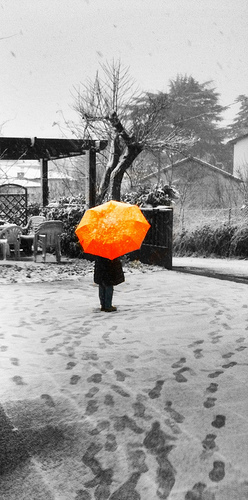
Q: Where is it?
A: This is at the pavement.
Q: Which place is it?
A: It is a pavement.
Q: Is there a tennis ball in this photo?
A: No, there are no tennis balls.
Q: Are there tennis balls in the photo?
A: No, there are no tennis balls.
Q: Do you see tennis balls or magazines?
A: No, there are no tennis balls or magazines.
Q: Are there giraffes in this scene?
A: No, there are no giraffes.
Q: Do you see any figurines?
A: No, there are no figurines.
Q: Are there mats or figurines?
A: No, there are no figurines or mats.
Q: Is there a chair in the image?
A: Yes, there is a chair.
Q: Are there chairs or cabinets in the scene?
A: Yes, there is a chair.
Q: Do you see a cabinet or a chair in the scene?
A: Yes, there is a chair.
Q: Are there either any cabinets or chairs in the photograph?
A: Yes, there is a chair.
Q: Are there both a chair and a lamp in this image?
A: No, there is a chair but no lamps.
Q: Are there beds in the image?
A: No, there are no beds.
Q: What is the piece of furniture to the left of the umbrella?
A: The piece of furniture is a chair.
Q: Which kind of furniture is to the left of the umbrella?
A: The piece of furniture is a chair.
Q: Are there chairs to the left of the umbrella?
A: Yes, there is a chair to the left of the umbrella.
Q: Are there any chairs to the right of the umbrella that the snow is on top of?
A: No, the chair is to the left of the umbrella.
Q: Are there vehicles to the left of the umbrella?
A: No, there is a chair to the left of the umbrella.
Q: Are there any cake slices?
A: No, there are no cake slices.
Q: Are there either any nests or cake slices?
A: No, there are no cake slices or nests.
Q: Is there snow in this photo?
A: Yes, there is snow.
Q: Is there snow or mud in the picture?
A: Yes, there is snow.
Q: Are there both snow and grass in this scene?
A: No, there is snow but no grass.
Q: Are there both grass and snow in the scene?
A: No, there is snow but no grass.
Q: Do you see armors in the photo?
A: No, there are no armors.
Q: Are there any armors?
A: No, there are no armors.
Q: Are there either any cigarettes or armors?
A: No, there are no armors or cigarettes.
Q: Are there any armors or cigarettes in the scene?
A: No, there are no armors or cigarettes.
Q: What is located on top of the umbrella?
A: The snow is on top of the umbrella.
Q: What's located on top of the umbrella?
A: The snow is on top of the umbrella.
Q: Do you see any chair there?
A: Yes, there is a chair.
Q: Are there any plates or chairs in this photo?
A: Yes, there is a chair.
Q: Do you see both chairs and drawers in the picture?
A: No, there is a chair but no drawers.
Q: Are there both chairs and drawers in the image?
A: No, there is a chair but no drawers.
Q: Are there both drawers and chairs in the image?
A: No, there is a chair but no drawers.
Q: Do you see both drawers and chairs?
A: No, there is a chair but no drawers.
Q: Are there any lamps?
A: No, there are no lamps.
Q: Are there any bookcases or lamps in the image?
A: No, there are no lamps or bookcases.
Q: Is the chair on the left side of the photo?
A: Yes, the chair is on the left of the image.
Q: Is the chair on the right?
A: No, the chair is on the left of the image.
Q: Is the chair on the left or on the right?
A: The chair is on the left of the image.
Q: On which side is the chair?
A: The chair is on the left of the image.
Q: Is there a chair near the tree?
A: Yes, there is a chair near the tree.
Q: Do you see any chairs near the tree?
A: Yes, there is a chair near the tree.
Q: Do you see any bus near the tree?
A: No, there is a chair near the tree.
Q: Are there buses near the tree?
A: No, there is a chair near the tree.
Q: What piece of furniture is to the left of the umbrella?
A: The piece of furniture is a chair.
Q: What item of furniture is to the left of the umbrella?
A: The piece of furniture is a chair.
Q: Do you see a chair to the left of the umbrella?
A: Yes, there is a chair to the left of the umbrella.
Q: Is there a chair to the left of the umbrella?
A: Yes, there is a chair to the left of the umbrella.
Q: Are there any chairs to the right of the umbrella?
A: No, the chair is to the left of the umbrella.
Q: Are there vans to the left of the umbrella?
A: No, there is a chair to the left of the umbrella.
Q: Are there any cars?
A: No, there are no cars.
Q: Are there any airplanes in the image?
A: No, there are no airplanes.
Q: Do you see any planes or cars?
A: No, there are no planes or cars.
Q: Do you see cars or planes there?
A: No, there are no planes or cars.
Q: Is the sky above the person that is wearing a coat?
A: Yes, the sky is above the person.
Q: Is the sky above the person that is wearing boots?
A: Yes, the sky is above the person.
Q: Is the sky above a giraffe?
A: No, the sky is above the person.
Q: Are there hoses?
A: No, there are no hoses.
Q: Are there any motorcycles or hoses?
A: No, there are no hoses or motorcycles.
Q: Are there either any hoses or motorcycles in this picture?
A: No, there are no hoses or motorcycles.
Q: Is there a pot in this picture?
A: No, there are no pots.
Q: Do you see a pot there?
A: No, there are no pots.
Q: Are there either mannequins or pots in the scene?
A: No, there are no pots or mannequins.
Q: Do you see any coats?
A: Yes, there is a coat.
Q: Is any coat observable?
A: Yes, there is a coat.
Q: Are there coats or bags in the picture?
A: Yes, there is a coat.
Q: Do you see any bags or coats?
A: Yes, there is a coat.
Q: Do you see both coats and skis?
A: No, there is a coat but no skis.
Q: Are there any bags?
A: No, there are no bags.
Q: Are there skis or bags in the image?
A: No, there are no bags or skis.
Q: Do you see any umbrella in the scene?
A: Yes, there is an umbrella.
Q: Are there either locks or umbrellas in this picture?
A: Yes, there is an umbrella.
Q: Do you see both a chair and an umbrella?
A: Yes, there are both an umbrella and a chair.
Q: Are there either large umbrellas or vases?
A: Yes, there is a large umbrella.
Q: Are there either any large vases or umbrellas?
A: Yes, there is a large umbrella.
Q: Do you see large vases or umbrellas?
A: Yes, there is a large umbrella.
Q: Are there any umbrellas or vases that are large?
A: Yes, the umbrella is large.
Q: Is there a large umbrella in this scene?
A: Yes, there is a large umbrella.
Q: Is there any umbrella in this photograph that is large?
A: Yes, there is an umbrella that is large.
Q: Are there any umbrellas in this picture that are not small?
A: Yes, there is a large umbrella.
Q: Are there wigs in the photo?
A: No, there are no wigs.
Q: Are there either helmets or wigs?
A: No, there are no wigs or helmets.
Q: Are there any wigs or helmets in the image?
A: No, there are no wigs or helmets.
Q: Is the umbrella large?
A: Yes, the umbrella is large.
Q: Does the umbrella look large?
A: Yes, the umbrella is large.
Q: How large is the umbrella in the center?
A: The umbrella is large.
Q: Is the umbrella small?
A: No, the umbrella is large.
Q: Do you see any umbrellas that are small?
A: No, there is an umbrella but it is large.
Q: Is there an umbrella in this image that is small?
A: No, there is an umbrella but it is large.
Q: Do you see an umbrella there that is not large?
A: No, there is an umbrella but it is large.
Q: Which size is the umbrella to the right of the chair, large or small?
A: The umbrella is large.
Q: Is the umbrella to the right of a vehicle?
A: No, the umbrella is to the right of the chair.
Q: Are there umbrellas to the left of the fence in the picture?
A: Yes, there is an umbrella to the left of the fence.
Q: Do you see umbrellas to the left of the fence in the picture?
A: Yes, there is an umbrella to the left of the fence.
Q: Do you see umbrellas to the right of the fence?
A: No, the umbrella is to the left of the fence.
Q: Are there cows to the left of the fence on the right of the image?
A: No, there is an umbrella to the left of the fence.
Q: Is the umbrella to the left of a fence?
A: Yes, the umbrella is to the left of a fence.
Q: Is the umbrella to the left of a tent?
A: No, the umbrella is to the left of a fence.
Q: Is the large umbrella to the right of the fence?
A: No, the umbrella is to the left of the fence.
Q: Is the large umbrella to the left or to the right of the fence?
A: The umbrella is to the left of the fence.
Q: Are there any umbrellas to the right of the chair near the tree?
A: Yes, there is an umbrella to the right of the chair.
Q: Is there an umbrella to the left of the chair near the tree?
A: No, the umbrella is to the right of the chair.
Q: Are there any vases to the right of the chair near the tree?
A: No, there is an umbrella to the right of the chair.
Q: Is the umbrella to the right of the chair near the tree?
A: Yes, the umbrella is to the right of the chair.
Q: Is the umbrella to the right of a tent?
A: No, the umbrella is to the right of the chair.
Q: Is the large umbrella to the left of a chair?
A: No, the umbrella is to the right of a chair.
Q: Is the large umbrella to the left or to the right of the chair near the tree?
A: The umbrella is to the right of the chair.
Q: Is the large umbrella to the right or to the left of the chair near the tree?
A: The umbrella is to the right of the chair.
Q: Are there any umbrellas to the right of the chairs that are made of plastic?
A: Yes, there is an umbrella to the right of the chairs.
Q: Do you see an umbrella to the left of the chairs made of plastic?
A: No, the umbrella is to the right of the chairs.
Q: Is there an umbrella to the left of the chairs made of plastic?
A: No, the umbrella is to the right of the chairs.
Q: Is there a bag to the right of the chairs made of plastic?
A: No, there is an umbrella to the right of the chairs.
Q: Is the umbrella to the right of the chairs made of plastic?
A: Yes, the umbrella is to the right of the chairs.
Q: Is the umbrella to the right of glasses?
A: No, the umbrella is to the right of the chairs.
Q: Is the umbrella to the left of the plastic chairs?
A: No, the umbrella is to the right of the chairs.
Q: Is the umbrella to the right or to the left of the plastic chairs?
A: The umbrella is to the right of the chairs.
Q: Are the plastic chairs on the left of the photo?
A: Yes, the chairs are on the left of the image.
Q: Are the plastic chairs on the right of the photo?
A: No, the chairs are on the left of the image.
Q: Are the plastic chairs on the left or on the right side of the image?
A: The chairs are on the left of the image.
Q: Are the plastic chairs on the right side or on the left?
A: The chairs are on the left of the image.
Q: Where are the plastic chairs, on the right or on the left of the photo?
A: The chairs are on the left of the image.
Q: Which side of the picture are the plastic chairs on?
A: The chairs are on the left of the image.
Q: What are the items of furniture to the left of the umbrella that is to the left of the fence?
A: The pieces of furniture are chairs.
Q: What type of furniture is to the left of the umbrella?
A: The pieces of furniture are chairs.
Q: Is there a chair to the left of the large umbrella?
A: Yes, there are chairs to the left of the umbrella.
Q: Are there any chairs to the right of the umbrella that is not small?
A: No, the chairs are to the left of the umbrella.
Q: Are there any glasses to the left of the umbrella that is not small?
A: No, there are chairs to the left of the umbrella.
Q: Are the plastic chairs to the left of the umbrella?
A: Yes, the chairs are to the left of the umbrella.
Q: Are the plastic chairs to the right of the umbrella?
A: No, the chairs are to the left of the umbrella.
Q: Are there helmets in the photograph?
A: No, there are no helmets.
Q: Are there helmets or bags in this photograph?
A: No, there are no helmets or bags.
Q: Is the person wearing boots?
A: Yes, the person is wearing boots.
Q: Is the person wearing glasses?
A: No, the person is wearing boots.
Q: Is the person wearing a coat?
A: Yes, the person is wearing a coat.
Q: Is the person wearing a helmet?
A: No, the person is wearing a coat.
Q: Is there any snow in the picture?
A: Yes, there is snow.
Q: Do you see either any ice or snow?
A: Yes, there is snow.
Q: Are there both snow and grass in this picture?
A: No, there is snow but no grass.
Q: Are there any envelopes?
A: No, there are no envelopes.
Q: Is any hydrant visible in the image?
A: No, there are no fire hydrants.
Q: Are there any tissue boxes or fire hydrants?
A: No, there are no fire hydrants or tissue boxes.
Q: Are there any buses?
A: No, there are no buses.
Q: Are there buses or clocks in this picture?
A: No, there are no buses or clocks.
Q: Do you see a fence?
A: Yes, there is a fence.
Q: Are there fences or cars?
A: Yes, there is a fence.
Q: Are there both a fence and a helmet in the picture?
A: No, there is a fence but no helmets.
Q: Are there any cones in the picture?
A: No, there are no cones.